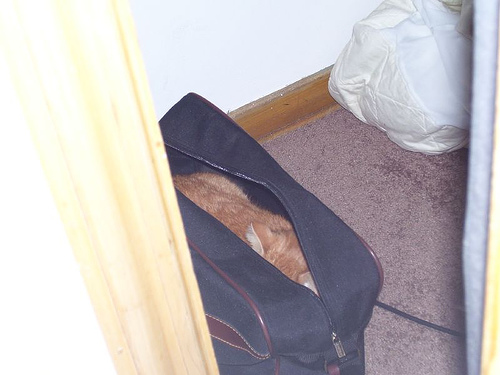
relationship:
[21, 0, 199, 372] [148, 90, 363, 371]
door frame near bag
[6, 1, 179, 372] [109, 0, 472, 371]
trim on door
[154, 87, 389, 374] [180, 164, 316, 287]
bag with cat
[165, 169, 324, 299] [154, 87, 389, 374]
cat in bag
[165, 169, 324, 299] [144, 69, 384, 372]
cat in bag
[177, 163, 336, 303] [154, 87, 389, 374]
cat in bag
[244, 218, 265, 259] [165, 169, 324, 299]
ears on cat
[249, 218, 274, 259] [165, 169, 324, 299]
ears on cat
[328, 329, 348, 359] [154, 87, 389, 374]
zipper on bag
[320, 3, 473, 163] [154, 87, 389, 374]
bag behind bag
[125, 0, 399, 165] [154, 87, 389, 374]
wall behind bag